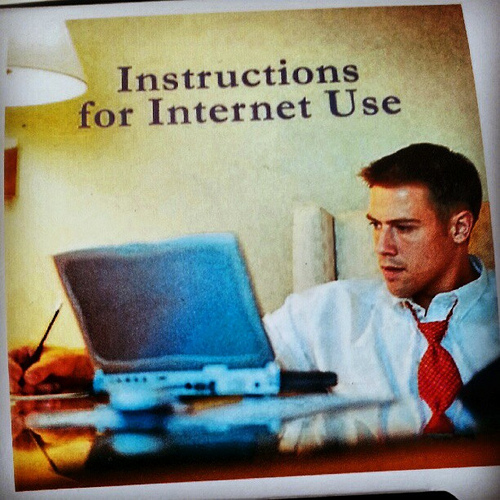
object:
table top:
[8, 382, 500, 500]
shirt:
[258, 251, 498, 444]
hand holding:
[10, 344, 57, 392]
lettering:
[196, 69, 214, 89]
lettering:
[181, 67, 197, 89]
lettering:
[160, 71, 179, 90]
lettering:
[135, 72, 159, 91]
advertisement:
[0, 1, 498, 499]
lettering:
[241, 66, 263, 88]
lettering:
[260, 64, 279, 87]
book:
[2, 0, 500, 498]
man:
[257, 139, 500, 459]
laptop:
[49, 224, 344, 408]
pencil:
[15, 301, 66, 381]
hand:
[6, 335, 98, 397]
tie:
[403, 298, 464, 436]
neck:
[420, 255, 476, 306]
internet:
[145, 93, 317, 129]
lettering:
[382, 92, 402, 115]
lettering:
[146, 97, 165, 127]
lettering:
[118, 102, 140, 130]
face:
[367, 186, 437, 290]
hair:
[355, 140, 486, 216]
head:
[361, 140, 477, 294]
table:
[9, 375, 500, 499]